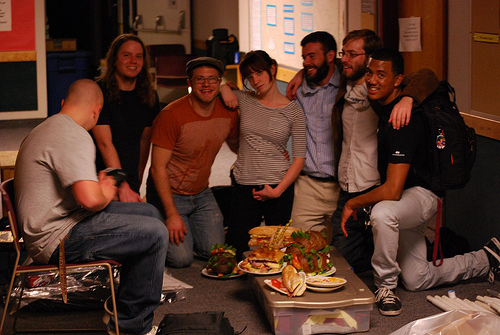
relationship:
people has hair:
[88, 34, 162, 203] [93, 30, 161, 102]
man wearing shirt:
[150, 56, 291, 268] [148, 87, 238, 193]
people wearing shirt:
[218, 50, 308, 261] [88, 69, 157, 154]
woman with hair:
[100, 35, 155, 180] [148, 68, 151, 88]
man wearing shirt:
[150, 56, 291, 268] [191, 124, 204, 152]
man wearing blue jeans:
[150, 56, 291, 268] [144, 187, 225, 268]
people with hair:
[218, 50, 308, 261] [245, 59, 267, 68]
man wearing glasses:
[150, 56, 291, 268] [184, 67, 226, 92]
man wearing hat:
[145, 52, 293, 269] [184, 54, 228, 81]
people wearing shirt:
[218, 50, 308, 261] [218, 49, 307, 255]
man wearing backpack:
[341, 51, 499, 317] [406, 72, 486, 176]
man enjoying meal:
[341, 51, 499, 317] [202, 218, 345, 296]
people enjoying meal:
[218, 50, 308, 261] [202, 218, 345, 296]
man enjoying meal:
[150, 56, 291, 268] [202, 218, 345, 296]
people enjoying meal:
[88, 34, 162, 203] [202, 218, 345, 296]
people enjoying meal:
[13, 79, 169, 335] [202, 218, 345, 296]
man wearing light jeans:
[341, 47, 499, 321] [373, 183, 490, 297]